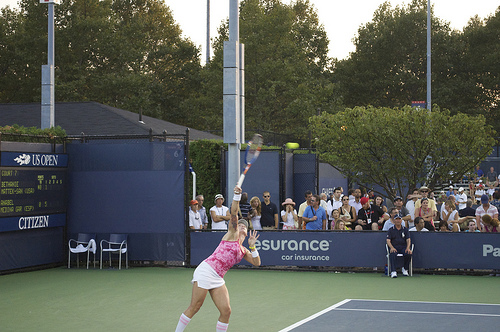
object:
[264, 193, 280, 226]
people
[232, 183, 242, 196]
hand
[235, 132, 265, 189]
tennis racket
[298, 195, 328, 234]
fan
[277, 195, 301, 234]
fan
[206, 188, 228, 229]
fan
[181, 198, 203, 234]
fan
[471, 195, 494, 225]
fan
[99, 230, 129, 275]
chair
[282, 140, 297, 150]
ball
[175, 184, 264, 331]
lady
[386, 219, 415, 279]
person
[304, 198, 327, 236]
person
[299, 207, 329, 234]
shirt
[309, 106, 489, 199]
tree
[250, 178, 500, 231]
audience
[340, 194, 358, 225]
people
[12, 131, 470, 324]
match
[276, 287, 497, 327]
court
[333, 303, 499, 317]
lines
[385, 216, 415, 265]
judge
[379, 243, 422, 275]
chair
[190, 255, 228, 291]
shorts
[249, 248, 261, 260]
wrist band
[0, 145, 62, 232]
scoreboard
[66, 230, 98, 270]
chair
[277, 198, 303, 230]
woman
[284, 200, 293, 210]
face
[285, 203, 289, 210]
hand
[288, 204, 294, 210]
hand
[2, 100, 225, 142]
roof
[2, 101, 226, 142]
building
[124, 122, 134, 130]
shingle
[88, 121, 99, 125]
shingle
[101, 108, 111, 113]
shingle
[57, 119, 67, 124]
shingle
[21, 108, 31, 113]
shingle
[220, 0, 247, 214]
light pole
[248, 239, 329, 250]
esurance sign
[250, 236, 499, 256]
white letters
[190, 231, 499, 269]
blue background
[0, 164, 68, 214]
scoreboard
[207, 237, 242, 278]
pink shirt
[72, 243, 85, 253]
towel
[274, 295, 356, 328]
white lines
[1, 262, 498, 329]
tennis court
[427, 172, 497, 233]
stands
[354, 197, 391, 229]
fans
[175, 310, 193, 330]
sock